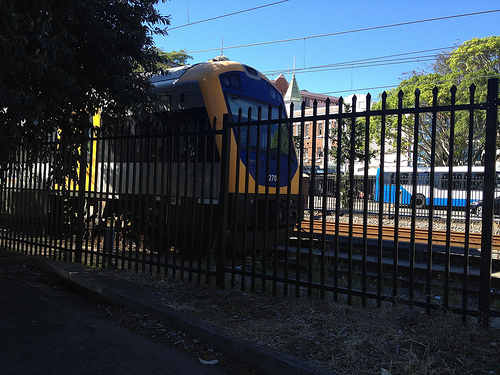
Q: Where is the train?
A: On the track.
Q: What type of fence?
A: Metal.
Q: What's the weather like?
A: Clear.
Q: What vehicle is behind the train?
A: Bus.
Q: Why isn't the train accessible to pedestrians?
A: There is a fence.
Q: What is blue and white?
A: Bus.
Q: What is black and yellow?
A: Train.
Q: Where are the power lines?
A: Above the train.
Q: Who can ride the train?
A: Passengers.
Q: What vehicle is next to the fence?
A: Train.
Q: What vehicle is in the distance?
A: Bus.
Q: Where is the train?
A: By the fence.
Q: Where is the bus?
A: By the tree.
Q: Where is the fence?
A: Next to the train.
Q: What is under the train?
A: Train tracks.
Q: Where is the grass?
A: On the ground.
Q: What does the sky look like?
A: Clear.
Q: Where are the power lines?
A: Above the train.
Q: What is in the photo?
A: Fence.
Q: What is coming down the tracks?
A: Train.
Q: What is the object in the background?
A: Bus.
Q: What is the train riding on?
A: Tracks.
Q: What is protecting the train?
A: Fence.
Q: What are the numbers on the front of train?
A: 270.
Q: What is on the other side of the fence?
A: A train.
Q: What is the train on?
A: Tracks.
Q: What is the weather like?
A: Sunny.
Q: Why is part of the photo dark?
A: Shade.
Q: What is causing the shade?
A: Trees.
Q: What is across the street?
A: Buildings.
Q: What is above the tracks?
A: Power lines.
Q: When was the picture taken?
A: Daytime.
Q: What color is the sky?
A: Blue.